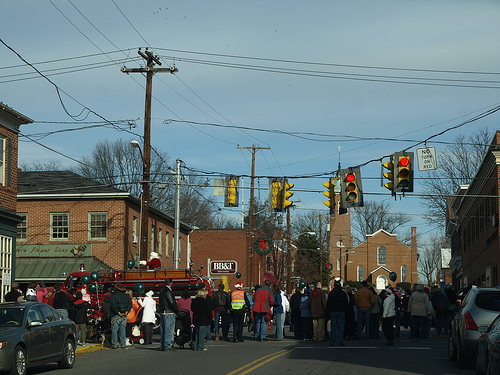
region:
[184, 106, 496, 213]
traffic lights hung on black wires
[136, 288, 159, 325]
woman wearing a white hat and jacket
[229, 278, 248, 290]
man wearing a festive red and white hat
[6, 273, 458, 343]
people congregated on a street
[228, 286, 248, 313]
a reflective orange and yellow vest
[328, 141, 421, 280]
church with a spire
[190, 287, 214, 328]
blonde woman wearing a black jacket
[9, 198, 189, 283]
green awning on lower level of brick building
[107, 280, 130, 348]
man standing with his hands behind his back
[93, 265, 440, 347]
a large crowd of people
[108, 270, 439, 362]
several people standing in the street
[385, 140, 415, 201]
a traffic signal hanging from a wite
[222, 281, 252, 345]
a man wearing a yellow and orange vest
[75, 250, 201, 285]
Santa Clause on the back of a Firetruck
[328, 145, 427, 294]
a brick church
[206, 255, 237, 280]
a BB&T bank sign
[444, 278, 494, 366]
a silver car parked on the side of the street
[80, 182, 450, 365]
a crowded city street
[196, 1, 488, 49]
a clear blue sky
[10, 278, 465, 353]
several people watching a parade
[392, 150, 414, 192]
stoplight is red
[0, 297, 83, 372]
car parked alongside road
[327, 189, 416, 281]
brown brick church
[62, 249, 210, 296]
fire truck is in the parade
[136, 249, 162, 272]
santa waving to parade watchers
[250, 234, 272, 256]
christmas wreath hanging on pole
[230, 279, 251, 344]
policeman wearing a santa hat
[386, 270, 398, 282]
green balloon is floating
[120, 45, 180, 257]
tall wooden electric pole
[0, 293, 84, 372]
vehicle on a street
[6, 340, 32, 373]
front wheel on a vehicle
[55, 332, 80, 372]
rear wheel on a vehicle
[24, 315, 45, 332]
side rear view mirror on a vehicle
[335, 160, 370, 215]
traffic signal on a cable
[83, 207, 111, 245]
window on a building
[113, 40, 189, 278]
utility pole near a street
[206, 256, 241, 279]
sign on a pole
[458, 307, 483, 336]
rear tail light on a vehicle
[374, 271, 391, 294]
white door on a church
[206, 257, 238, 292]
A banking sign on a white post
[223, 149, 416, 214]
A group of traffic lights hung from wires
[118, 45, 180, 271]
A utility pole with several wires attached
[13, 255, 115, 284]
A green awning on a brick building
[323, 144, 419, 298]
A brick church with a tall steeple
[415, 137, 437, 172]
A no turn on red sign hanging on a wire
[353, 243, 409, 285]
Church stained glass windows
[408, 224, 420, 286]
A brick chimney on the side of a building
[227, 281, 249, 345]
A person wearing a safety vest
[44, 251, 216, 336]
A firetruck with Santa riding on top